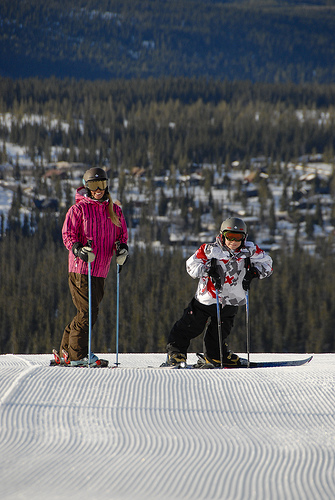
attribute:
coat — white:
[62, 189, 130, 280]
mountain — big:
[8, 7, 331, 74]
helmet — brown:
[213, 214, 251, 238]